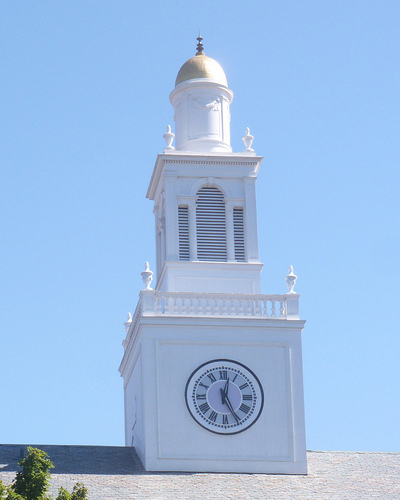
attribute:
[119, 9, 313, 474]
tower — white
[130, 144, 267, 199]
roof — building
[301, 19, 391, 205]
sky — clear, blue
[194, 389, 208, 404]
number — 9